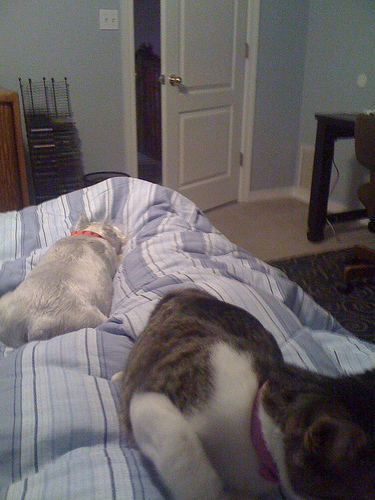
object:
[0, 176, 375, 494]
bed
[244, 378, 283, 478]
collar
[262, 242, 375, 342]
rug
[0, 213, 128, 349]
cat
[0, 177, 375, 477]
blue comforter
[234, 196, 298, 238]
floor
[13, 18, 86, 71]
wall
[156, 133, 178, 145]
door knob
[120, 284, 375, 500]
cat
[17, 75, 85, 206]
rack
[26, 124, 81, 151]
cd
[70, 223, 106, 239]
collar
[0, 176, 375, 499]
blanket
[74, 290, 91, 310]
ear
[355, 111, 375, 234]
chair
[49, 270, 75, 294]
fur